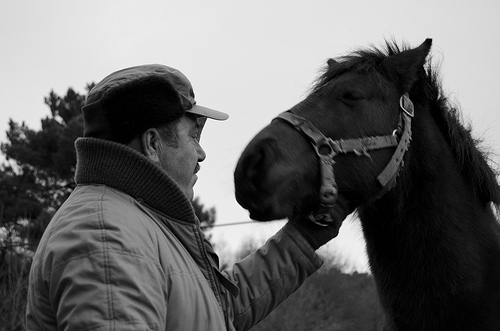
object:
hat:
[79, 62, 231, 140]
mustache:
[194, 162, 202, 174]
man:
[23, 62, 359, 331]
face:
[228, 38, 413, 224]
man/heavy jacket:
[21, 133, 326, 331]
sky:
[0, 0, 500, 276]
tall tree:
[0, 78, 219, 331]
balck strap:
[274, 94, 418, 218]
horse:
[229, 35, 500, 331]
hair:
[303, 34, 441, 102]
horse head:
[226, 30, 451, 227]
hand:
[288, 205, 353, 245]